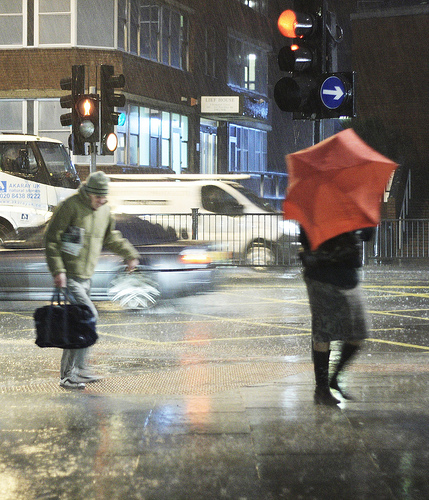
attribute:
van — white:
[122, 175, 254, 215]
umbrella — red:
[277, 124, 402, 254]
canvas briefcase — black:
[30, 296, 107, 356]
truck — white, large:
[5, 136, 67, 211]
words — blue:
[0, 182, 46, 211]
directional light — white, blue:
[317, 63, 349, 116]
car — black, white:
[133, 224, 212, 297]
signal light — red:
[74, 99, 96, 120]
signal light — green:
[117, 112, 127, 127]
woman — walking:
[277, 134, 393, 413]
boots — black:
[311, 385, 352, 411]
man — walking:
[37, 170, 145, 395]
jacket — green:
[50, 214, 103, 278]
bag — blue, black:
[47, 318, 81, 336]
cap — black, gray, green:
[85, 173, 109, 189]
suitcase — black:
[70, 316, 100, 344]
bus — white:
[13, 133, 63, 188]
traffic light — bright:
[68, 87, 115, 155]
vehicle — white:
[150, 168, 277, 219]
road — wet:
[124, 423, 334, 484]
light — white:
[165, 273, 245, 304]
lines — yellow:
[376, 275, 426, 352]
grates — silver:
[110, 371, 185, 409]